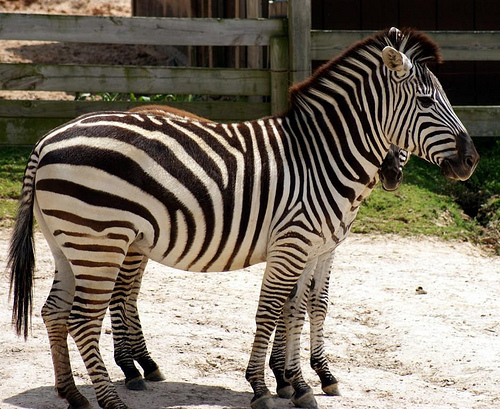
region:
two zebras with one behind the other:
[25, 16, 480, 397]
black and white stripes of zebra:
[178, 162, 270, 230]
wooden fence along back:
[10, 6, 345, 138]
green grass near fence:
[397, 180, 470, 230]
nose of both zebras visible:
[366, 131, 488, 193]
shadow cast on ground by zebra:
[29, 356, 296, 403]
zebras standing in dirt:
[228, 310, 408, 398]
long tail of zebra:
[7, 153, 44, 334]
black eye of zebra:
[400, 81, 460, 126]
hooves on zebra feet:
[126, 364, 182, 390]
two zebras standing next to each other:
[12, 30, 472, 400]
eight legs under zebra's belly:
[30, 102, 375, 403]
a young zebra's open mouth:
[365, 131, 416, 206]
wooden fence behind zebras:
[15, 5, 492, 170]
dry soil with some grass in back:
[20, 230, 475, 397]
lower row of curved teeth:
[372, 165, 402, 195]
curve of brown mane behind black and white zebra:
[120, 87, 255, 122]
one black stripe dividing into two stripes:
[157, 160, 197, 270]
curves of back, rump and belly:
[12, 100, 267, 280]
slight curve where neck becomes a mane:
[276, 48, 372, 125]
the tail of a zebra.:
[0, 141, 57, 341]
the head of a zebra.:
[335, 21, 482, 224]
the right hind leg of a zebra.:
[38, 211, 145, 406]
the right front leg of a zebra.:
[220, 218, 319, 406]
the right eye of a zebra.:
[404, 82, 443, 124]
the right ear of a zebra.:
[373, 41, 420, 79]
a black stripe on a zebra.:
[242, 118, 270, 280]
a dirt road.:
[0, 236, 497, 407]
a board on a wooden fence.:
[0, 63, 271, 90]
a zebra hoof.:
[320, 376, 350, 399]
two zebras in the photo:
[26, 41, 466, 393]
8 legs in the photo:
[34, 255, 373, 402]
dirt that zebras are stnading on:
[359, 260, 481, 340]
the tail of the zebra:
[10, 171, 38, 349]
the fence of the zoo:
[9, 15, 279, 98]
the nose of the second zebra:
[386, 163, 425, 199]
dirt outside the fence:
[18, 44, 123, 77]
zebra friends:
[24, 49, 479, 406]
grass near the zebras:
[382, 173, 451, 213]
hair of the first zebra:
[269, 28, 439, 83]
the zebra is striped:
[57, 88, 443, 383]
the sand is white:
[358, 254, 492, 404]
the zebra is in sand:
[70, 80, 448, 401]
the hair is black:
[11, 207, 51, 344]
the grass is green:
[366, 183, 458, 244]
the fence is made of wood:
[14, 7, 363, 109]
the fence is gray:
[2, 15, 306, 105]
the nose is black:
[458, 133, 478, 163]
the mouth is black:
[445, 135, 486, 189]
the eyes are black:
[419, 84, 444, 128]